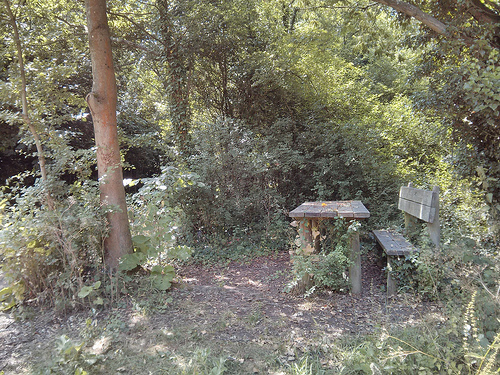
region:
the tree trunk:
[82, 6, 152, 294]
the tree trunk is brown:
[80, 1, 140, 276]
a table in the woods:
[270, 200, 380, 292]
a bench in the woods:
[375, 150, 445, 290]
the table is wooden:
[275, 190, 378, 300]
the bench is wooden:
[375, 178, 443, 294]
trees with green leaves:
[188, 5, 385, 175]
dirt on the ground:
[162, 285, 270, 350]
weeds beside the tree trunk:
[126, 235, 202, 307]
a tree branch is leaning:
[399, 2, 485, 62]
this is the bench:
[359, 175, 457, 305]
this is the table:
[257, 178, 370, 311]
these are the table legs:
[293, 219, 375, 300]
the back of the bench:
[388, 176, 460, 240]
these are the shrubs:
[180, 115, 274, 209]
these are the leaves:
[294, 89, 396, 139]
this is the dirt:
[187, 281, 255, 350]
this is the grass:
[91, 330, 190, 373]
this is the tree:
[72, 62, 161, 294]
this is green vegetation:
[172, 87, 281, 196]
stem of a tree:
[88, 146, 128, 226]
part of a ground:
[228, 288, 285, 358]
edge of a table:
[327, 210, 353, 228]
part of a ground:
[192, 300, 239, 357]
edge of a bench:
[383, 236, 424, 272]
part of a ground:
[218, 272, 268, 327]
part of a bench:
[407, 217, 442, 279]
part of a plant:
[104, 234, 146, 289]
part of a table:
[338, 234, 346, 252]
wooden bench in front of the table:
[372, 180, 441, 297]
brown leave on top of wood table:
[290, 199, 371, 217]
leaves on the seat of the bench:
[372, 227, 418, 255]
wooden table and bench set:
[287, 182, 443, 299]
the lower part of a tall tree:
[82, 2, 134, 268]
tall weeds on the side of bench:
[372, 220, 453, 300]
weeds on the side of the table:
[290, 217, 362, 292]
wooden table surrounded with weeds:
[287, 180, 371, 297]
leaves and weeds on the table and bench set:
[286, 178, 441, 299]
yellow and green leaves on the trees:
[0, 0, 492, 131]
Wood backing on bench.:
[393, 182, 448, 238]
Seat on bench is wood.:
[379, 221, 411, 272]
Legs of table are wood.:
[279, 225, 373, 275]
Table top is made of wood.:
[307, 181, 367, 229]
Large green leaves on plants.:
[122, 235, 181, 306]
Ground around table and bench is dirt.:
[190, 271, 400, 329]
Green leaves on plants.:
[197, 131, 287, 225]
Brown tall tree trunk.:
[80, 48, 145, 277]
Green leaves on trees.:
[425, 49, 483, 168]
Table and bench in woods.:
[211, 162, 467, 302]